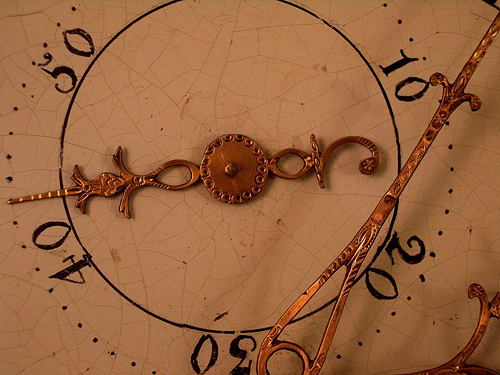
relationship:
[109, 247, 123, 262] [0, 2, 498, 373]
mark on background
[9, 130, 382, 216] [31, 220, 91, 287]
dial past 40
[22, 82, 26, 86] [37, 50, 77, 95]
dot behind number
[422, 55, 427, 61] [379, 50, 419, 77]
dot behind number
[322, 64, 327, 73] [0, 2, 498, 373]
speck on background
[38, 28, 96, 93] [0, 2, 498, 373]
50 on background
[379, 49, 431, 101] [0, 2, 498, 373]
10 on background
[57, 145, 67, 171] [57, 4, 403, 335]
edge of a circle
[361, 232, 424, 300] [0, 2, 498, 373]
20 on background